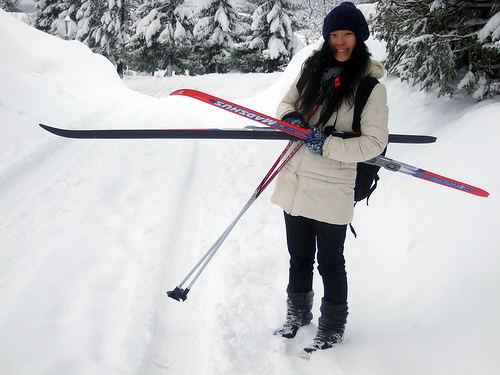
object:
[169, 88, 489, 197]
ski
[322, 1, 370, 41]
cap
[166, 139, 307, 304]
poles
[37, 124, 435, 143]
ski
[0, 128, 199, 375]
tracks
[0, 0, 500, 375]
snow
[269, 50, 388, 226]
jacket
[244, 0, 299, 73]
tree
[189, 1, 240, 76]
tree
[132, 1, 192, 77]
tree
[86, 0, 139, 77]
tree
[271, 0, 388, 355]
lady